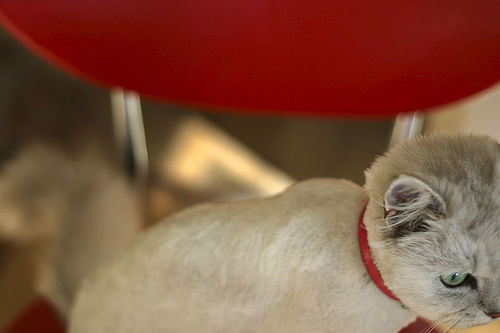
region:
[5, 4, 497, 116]
semi circular portion of red table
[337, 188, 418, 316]
red collar on a white cat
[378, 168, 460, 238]
black and white ear of a cat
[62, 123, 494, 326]
white cat with gray and black highlights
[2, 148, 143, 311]
long white and gray tail of a cat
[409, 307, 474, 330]
white and black whiskers of a cat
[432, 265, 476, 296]
blue and yellow eye of a cat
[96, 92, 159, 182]
blurry light legs of a red table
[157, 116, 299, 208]
very blurry book or newspaper on the floor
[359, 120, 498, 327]
head and neck of a white gray and black cat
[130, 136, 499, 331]
grey kitten on chair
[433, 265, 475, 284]
blue eye of kitten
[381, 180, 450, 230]
ear of the kitten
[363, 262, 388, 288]
red collar on kitten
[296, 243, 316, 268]
grey fur on kitten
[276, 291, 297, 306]
grey fur on kitten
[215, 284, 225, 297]
grey fur on kitten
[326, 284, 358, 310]
grey fur on kitten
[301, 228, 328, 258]
grey fur on kitten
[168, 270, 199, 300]
grey fur on kitten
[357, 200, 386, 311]
A bright red collar.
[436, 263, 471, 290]
A green cat's eye.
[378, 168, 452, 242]
A perked up cat's ear.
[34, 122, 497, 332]
A curious cat staring downward.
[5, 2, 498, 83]
A red chair back.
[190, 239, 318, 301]
Beige cat fur.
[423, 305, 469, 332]
Tall whiskers protruding from the cat's face.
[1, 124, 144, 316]
The bushy tail of the cat.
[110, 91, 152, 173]
A metal, chrome colored chair support.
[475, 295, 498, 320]
A cat's nose, next to the whiskers.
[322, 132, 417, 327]
cat is wearing a collar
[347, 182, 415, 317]
cat is wearing a collar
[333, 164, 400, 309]
the collar is red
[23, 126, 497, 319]
white cat on a chair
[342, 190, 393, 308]
red collar on the cat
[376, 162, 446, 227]
ear on the cat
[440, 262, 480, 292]
eye on the cat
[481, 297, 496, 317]
nose on the cat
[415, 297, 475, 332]
whiskers on the cat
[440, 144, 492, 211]
fur on the cat's head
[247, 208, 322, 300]
fur on the cat's back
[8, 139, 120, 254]
tail on the cat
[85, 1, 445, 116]
chair with a cat on it